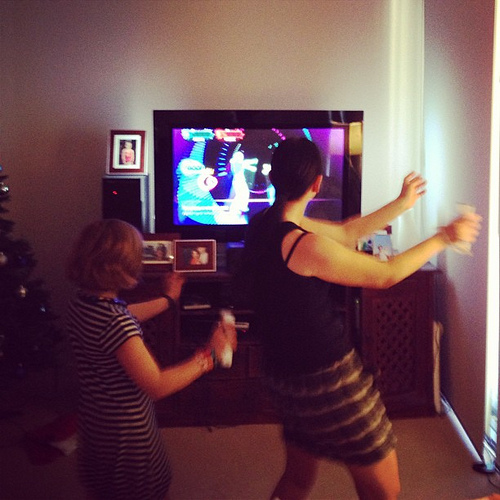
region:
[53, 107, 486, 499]
Two young women in the foreground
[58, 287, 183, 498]
Young girl is wearing a striped dress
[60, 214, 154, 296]
Young girl has brown colored hair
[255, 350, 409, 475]
Adult woman is wearing a skirt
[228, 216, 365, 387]
Woman is wearing a black tank top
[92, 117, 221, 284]
Picture frames in the background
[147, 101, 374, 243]
A Flat screen TV in the background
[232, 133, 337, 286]
Woman has her hair in a pony tail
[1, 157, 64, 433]
The side view of a christmas tree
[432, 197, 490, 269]
Woman is holding a white controller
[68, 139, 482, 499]
Two people playing video games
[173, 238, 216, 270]
A framed picture on top of a media center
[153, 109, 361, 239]
A flat screen television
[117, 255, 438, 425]
A brown wooden media center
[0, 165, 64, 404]
An unlit Christmas tree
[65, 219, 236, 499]
A girl wearing a stripped dress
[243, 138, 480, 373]
A woman wearing a black shirt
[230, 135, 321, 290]
A woman with her hair in a ponytail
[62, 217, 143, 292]
Short light hair on a girl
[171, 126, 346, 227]
Video game shown on the screen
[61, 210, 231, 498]
A girl in a striped dress.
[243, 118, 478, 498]
A lady in a striped skirt and black top.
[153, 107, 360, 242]
A flat screen television.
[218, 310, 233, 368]
A video game controller.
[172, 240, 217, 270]
A picture of two people in a frame.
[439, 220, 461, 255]
A strap to the video game controller.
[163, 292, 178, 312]
A watch band.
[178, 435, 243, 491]
The beige carpet on the floor.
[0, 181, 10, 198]
A christmas ball ornament.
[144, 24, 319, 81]
The white walls.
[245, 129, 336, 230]
head of a person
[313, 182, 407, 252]
arm of a person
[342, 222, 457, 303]
arm of a person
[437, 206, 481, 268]
hand of a person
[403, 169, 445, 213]
fingers of a person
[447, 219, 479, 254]
fingers of a person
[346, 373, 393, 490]
leg of a person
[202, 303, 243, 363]
hand of a person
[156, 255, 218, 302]
hand of a person